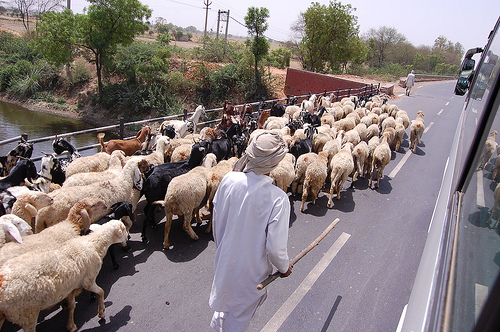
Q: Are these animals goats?
A: No, there are both sheep and goats.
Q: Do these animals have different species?
A: Yes, they are sheep and goats.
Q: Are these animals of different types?
A: Yes, they are sheep and goats.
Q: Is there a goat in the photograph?
A: Yes, there are goats.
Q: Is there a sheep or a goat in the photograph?
A: Yes, there are goats.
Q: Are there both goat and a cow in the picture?
A: No, there are goats but no cows.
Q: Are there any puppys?
A: No, there are no puppys.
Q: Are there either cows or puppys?
A: No, there are no puppys or cows.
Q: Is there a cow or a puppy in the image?
A: No, there are no puppys or cows.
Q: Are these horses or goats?
A: These are goats.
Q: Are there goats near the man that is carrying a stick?
A: Yes, there are goats near the man.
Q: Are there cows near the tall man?
A: No, there are goats near the man.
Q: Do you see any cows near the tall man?
A: No, there are goats near the man.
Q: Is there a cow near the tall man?
A: No, there are goats near the man.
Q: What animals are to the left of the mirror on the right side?
A: The animals are goats.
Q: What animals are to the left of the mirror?
A: The animals are goats.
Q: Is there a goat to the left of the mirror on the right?
A: Yes, there are goats to the left of the mirror.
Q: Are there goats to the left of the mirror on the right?
A: Yes, there are goats to the left of the mirror.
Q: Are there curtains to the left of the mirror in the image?
A: No, there are goats to the left of the mirror.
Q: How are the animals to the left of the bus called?
A: The animals are goats.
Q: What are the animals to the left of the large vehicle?
A: The animals are goats.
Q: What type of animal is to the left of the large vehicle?
A: The animals are goats.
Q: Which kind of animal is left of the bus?
A: The animals are goats.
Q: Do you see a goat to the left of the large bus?
A: Yes, there are goats to the left of the bus.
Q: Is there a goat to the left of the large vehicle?
A: Yes, there are goats to the left of the bus.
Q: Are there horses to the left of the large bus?
A: No, there are goats to the left of the bus.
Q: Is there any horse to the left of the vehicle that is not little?
A: No, there are goats to the left of the bus.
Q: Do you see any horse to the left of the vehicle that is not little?
A: No, there are goats to the left of the bus.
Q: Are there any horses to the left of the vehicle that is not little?
A: No, there are goats to the left of the bus.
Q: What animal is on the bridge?
A: The goats are on the bridge.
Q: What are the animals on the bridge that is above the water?
A: The animals are goats.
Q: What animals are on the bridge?
A: The animals are goats.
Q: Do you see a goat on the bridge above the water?
A: Yes, there are goats on the bridge.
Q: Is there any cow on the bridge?
A: No, there are goats on the bridge.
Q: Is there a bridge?
A: Yes, there is a bridge.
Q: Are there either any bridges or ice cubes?
A: Yes, there is a bridge.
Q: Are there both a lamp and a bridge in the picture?
A: No, there is a bridge but no lamps.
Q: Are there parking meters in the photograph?
A: No, there are no parking meters.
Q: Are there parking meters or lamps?
A: No, there are no parking meters or lamps.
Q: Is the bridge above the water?
A: Yes, the bridge is above the water.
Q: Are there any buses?
A: Yes, there is a bus.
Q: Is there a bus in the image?
A: Yes, there is a bus.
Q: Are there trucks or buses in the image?
A: Yes, there is a bus.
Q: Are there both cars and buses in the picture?
A: No, there is a bus but no cars.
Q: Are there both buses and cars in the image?
A: No, there is a bus but no cars.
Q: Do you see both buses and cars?
A: No, there is a bus but no cars.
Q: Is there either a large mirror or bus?
A: Yes, there is a large bus.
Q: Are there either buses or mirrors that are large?
A: Yes, the bus is large.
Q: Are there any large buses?
A: Yes, there is a large bus.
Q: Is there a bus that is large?
A: Yes, there is a bus that is large.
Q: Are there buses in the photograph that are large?
A: Yes, there is a bus that is large.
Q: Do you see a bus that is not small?
A: Yes, there is a large bus.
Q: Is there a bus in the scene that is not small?
A: Yes, there is a large bus.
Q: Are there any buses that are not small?
A: Yes, there is a large bus.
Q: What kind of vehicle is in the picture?
A: The vehicle is a bus.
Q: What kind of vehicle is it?
A: The vehicle is a bus.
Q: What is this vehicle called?
A: This is a bus.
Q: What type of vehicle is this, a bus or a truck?
A: This is a bus.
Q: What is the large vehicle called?
A: The vehicle is a bus.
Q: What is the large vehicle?
A: The vehicle is a bus.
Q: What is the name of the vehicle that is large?
A: The vehicle is a bus.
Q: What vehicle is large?
A: The vehicle is a bus.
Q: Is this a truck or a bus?
A: This is a bus.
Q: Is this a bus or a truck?
A: This is a bus.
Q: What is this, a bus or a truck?
A: This is a bus.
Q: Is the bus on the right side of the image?
A: Yes, the bus is on the right of the image.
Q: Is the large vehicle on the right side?
A: Yes, the bus is on the right of the image.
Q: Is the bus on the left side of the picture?
A: No, the bus is on the right of the image.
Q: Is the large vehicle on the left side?
A: No, the bus is on the right of the image.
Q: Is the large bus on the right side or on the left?
A: The bus is on the right of the image.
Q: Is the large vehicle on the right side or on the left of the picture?
A: The bus is on the right of the image.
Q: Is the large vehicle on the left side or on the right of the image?
A: The bus is on the right of the image.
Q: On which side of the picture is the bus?
A: The bus is on the right of the image.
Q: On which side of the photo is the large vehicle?
A: The bus is on the right of the image.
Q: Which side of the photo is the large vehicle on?
A: The bus is on the right of the image.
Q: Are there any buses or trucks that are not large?
A: No, there is a bus but it is large.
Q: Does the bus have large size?
A: Yes, the bus is large.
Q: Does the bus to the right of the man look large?
A: Yes, the bus is large.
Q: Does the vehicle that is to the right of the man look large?
A: Yes, the bus is large.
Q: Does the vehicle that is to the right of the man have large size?
A: Yes, the bus is large.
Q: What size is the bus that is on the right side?
A: The bus is large.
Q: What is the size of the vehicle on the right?
A: The bus is large.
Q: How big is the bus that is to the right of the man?
A: The bus is large.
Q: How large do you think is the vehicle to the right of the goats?
A: The bus is large.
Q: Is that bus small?
A: No, the bus is large.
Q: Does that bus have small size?
A: No, the bus is large.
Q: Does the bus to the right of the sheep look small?
A: No, the bus is large.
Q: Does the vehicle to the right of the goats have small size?
A: No, the bus is large.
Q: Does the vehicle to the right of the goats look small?
A: No, the bus is large.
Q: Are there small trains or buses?
A: No, there is a bus but it is large.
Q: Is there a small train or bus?
A: No, there is a bus but it is large.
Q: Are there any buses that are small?
A: No, there is a bus but it is large.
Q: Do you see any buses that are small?
A: No, there is a bus but it is large.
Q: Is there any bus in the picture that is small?
A: No, there is a bus but it is large.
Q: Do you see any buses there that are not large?
A: No, there is a bus but it is large.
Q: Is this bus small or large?
A: The bus is large.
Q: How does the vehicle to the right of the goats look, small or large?
A: The bus is large.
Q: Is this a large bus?
A: Yes, this is a large bus.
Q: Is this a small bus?
A: No, this is a large bus.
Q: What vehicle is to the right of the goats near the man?
A: The vehicle is a bus.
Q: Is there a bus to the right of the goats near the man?
A: Yes, there is a bus to the right of the goats.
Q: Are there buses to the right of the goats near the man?
A: Yes, there is a bus to the right of the goats.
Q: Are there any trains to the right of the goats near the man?
A: No, there is a bus to the right of the goats.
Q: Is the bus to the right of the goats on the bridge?
A: Yes, the bus is to the right of the goats.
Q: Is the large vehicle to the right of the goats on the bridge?
A: Yes, the bus is to the right of the goats.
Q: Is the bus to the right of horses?
A: No, the bus is to the right of the goats.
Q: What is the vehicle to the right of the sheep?
A: The vehicle is a bus.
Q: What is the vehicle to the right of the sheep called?
A: The vehicle is a bus.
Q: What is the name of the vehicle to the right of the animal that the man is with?
A: The vehicle is a bus.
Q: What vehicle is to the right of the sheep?
A: The vehicle is a bus.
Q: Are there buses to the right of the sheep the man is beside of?
A: Yes, there is a bus to the right of the sheep.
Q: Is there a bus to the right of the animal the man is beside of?
A: Yes, there is a bus to the right of the sheep.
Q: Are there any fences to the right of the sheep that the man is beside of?
A: No, there is a bus to the right of the sheep.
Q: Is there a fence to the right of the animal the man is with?
A: No, there is a bus to the right of the sheep.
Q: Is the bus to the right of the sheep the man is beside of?
A: Yes, the bus is to the right of the sheep.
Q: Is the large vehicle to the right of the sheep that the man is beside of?
A: Yes, the bus is to the right of the sheep.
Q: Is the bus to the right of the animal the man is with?
A: Yes, the bus is to the right of the sheep.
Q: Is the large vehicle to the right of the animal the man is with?
A: Yes, the bus is to the right of the sheep.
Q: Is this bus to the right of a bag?
A: No, the bus is to the right of the sheep.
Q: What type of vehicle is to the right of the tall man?
A: The vehicle is a bus.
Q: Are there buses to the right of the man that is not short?
A: Yes, there is a bus to the right of the man.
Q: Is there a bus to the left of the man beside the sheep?
A: No, the bus is to the right of the man.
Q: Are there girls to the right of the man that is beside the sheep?
A: No, there is a bus to the right of the man.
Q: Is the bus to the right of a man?
A: Yes, the bus is to the right of a man.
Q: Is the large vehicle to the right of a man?
A: Yes, the bus is to the right of a man.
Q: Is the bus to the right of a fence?
A: No, the bus is to the right of a man.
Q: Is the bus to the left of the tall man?
A: No, the bus is to the right of the man.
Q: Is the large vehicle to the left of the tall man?
A: No, the bus is to the right of the man.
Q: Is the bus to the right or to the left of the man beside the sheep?
A: The bus is to the right of the man.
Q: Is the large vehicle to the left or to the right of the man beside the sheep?
A: The bus is to the right of the man.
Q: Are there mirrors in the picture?
A: Yes, there is a mirror.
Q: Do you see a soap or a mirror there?
A: Yes, there is a mirror.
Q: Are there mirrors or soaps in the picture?
A: Yes, there is a mirror.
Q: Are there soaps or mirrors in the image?
A: Yes, there is a mirror.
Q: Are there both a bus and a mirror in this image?
A: Yes, there are both a mirror and a bus.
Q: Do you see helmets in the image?
A: No, there are no helmets.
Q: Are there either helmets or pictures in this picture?
A: No, there are no helmets or pictures.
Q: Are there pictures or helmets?
A: No, there are no helmets or pictures.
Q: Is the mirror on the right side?
A: Yes, the mirror is on the right of the image.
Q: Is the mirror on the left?
A: No, the mirror is on the right of the image.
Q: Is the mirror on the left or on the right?
A: The mirror is on the right of the image.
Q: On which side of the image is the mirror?
A: The mirror is on the right of the image.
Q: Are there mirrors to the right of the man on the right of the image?
A: Yes, there is a mirror to the right of the man.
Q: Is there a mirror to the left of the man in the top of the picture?
A: No, the mirror is to the right of the man.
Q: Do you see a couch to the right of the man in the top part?
A: No, there is a mirror to the right of the man.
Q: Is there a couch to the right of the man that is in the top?
A: No, there is a mirror to the right of the man.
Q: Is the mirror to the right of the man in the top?
A: Yes, the mirror is to the right of the man.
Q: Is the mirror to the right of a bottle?
A: No, the mirror is to the right of the man.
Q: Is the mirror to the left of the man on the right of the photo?
A: No, the mirror is to the right of the man.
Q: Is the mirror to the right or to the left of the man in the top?
A: The mirror is to the right of the man.